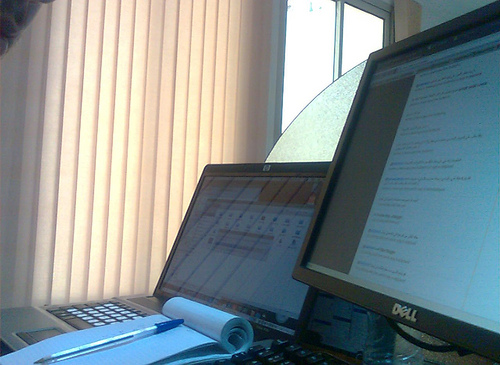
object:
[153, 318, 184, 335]
cap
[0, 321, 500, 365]
table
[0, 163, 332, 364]
laptop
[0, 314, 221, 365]
pages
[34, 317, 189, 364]
pen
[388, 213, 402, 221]
words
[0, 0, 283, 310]
blinds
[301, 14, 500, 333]
screen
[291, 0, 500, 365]
dell monitor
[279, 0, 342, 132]
window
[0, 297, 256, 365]
notepad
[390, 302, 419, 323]
logo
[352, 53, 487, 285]
writing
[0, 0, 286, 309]
wall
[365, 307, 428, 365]
bottle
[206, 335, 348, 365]
keyboard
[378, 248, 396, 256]
words